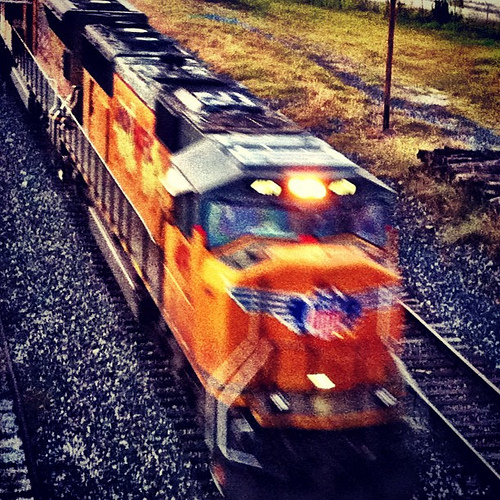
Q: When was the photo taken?
A: Daytime.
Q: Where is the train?
A: Tracks.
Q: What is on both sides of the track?
A: Gravel.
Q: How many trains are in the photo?
A: One.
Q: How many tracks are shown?
A: Three.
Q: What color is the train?
A: Black and orange.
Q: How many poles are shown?
A: One.